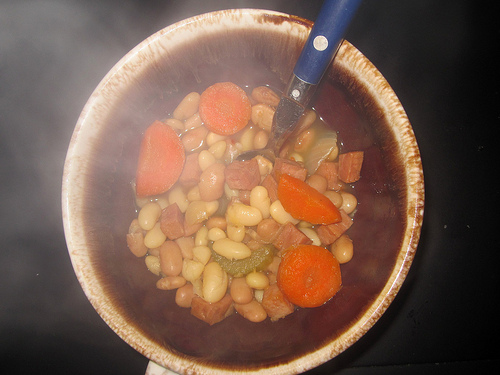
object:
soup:
[101, 74, 379, 333]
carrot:
[138, 121, 186, 200]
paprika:
[302, 130, 337, 177]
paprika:
[208, 242, 282, 278]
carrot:
[198, 81, 249, 138]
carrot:
[277, 175, 341, 226]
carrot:
[276, 242, 345, 311]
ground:
[324, 184, 346, 211]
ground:
[427, 154, 444, 184]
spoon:
[236, 0, 361, 186]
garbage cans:
[135, 136, 367, 309]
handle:
[263, 5, 356, 159]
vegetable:
[133, 79, 366, 319]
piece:
[276, 245, 344, 308]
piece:
[277, 172, 343, 226]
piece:
[218, 101, 239, 117]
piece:
[161, 151, 171, 160]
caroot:
[278, 245, 342, 312]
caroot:
[276, 175, 341, 226]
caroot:
[197, 80, 253, 137]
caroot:
[137, 122, 187, 198]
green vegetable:
[207, 240, 276, 277]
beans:
[126, 88, 360, 324]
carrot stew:
[133, 81, 344, 309]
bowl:
[60, 10, 428, 372]